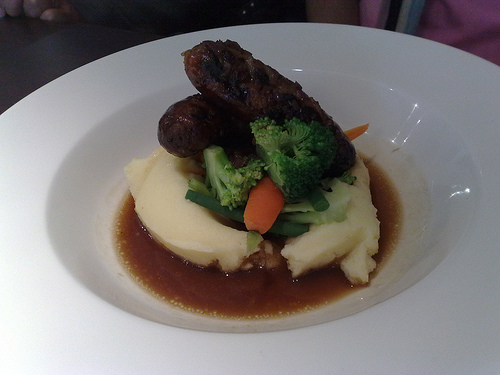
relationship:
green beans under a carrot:
[282, 221, 296, 233] [255, 199, 276, 220]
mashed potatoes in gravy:
[343, 205, 366, 229] [224, 277, 281, 304]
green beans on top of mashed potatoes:
[282, 221, 296, 233] [343, 205, 366, 229]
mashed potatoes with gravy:
[343, 205, 366, 229] [224, 277, 281, 304]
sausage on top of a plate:
[178, 35, 263, 95] [409, 63, 457, 124]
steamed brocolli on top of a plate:
[253, 122, 325, 188] [409, 63, 457, 124]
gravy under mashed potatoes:
[224, 277, 281, 304] [343, 205, 366, 229]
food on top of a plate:
[111, 29, 390, 290] [409, 63, 457, 124]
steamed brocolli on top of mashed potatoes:
[253, 122, 325, 188] [343, 205, 366, 229]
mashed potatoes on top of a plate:
[343, 205, 366, 229] [409, 63, 457, 124]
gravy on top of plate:
[224, 277, 281, 304] [409, 63, 457, 124]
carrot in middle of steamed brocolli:
[255, 199, 276, 220] [253, 122, 325, 188]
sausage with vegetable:
[178, 35, 263, 95] [250, 114, 334, 195]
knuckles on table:
[2, 2, 62, 19] [18, 32, 78, 60]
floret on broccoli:
[283, 123, 334, 167] [247, 116, 343, 198]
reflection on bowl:
[390, 101, 424, 151] [6, 19, 496, 369]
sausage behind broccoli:
[178, 35, 263, 95] [252, 119, 340, 193]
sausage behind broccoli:
[178, 35, 263, 95] [198, 143, 256, 208]